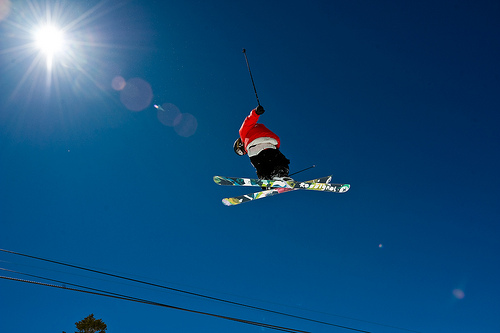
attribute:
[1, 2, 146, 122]
sun — shining, bright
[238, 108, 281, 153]
jacket — red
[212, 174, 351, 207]
skis — multicolored, crossed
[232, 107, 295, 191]
person — outdoors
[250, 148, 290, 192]
pants — black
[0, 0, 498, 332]
sky — blue, clear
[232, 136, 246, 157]
helmet — black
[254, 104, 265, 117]
glove — black